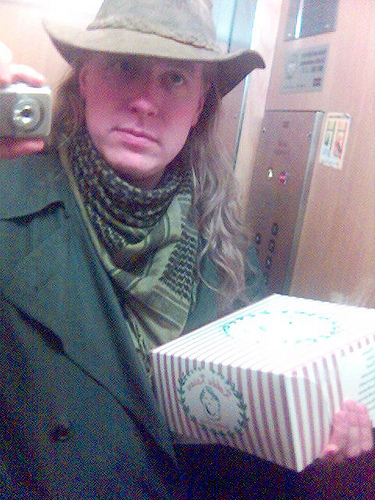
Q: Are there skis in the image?
A: No, there are no skis.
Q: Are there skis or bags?
A: No, there are no skis or bags.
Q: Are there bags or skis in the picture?
A: No, there are no skis or bags.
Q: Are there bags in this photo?
A: No, there are no bags.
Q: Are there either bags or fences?
A: No, there are no bags or fences.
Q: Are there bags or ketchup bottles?
A: No, there are no bags or ketchup bottles.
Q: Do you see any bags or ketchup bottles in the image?
A: No, there are no bags or ketchup bottles.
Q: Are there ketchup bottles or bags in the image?
A: No, there are no bags or ketchup bottles.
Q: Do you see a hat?
A: Yes, there is a hat.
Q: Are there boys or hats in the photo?
A: Yes, there is a hat.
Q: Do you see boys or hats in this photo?
A: Yes, there is a hat.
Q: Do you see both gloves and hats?
A: No, there is a hat but no gloves.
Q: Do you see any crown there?
A: No, there are no crowns.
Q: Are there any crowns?
A: No, there are no crowns.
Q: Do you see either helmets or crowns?
A: No, there are no crowns or helmets.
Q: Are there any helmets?
A: No, there are no helmets.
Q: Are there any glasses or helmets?
A: No, there are no helmets or glasses.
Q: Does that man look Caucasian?
A: Yes, the man is caucasian.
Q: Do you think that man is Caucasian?
A: Yes, the man is caucasian.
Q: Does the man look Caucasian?
A: Yes, the man is caucasian.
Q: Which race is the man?
A: The man is caucasian.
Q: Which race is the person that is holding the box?
A: The man is caucasian.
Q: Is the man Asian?
A: No, the man is caucasian.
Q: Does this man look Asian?
A: No, the man is caucasian.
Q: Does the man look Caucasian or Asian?
A: The man is caucasian.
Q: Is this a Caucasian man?
A: Yes, this is a Caucasian man.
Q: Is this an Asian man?
A: No, this is a Caucasian man.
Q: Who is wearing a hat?
A: The man is wearing a hat.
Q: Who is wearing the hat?
A: The man is wearing a hat.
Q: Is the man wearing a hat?
A: Yes, the man is wearing a hat.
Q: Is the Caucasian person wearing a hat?
A: Yes, the man is wearing a hat.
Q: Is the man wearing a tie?
A: No, the man is wearing a hat.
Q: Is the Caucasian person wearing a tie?
A: No, the man is wearing a hat.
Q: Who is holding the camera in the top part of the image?
A: The man is holding the camera.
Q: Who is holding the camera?
A: The man is holding the camera.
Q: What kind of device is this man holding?
A: The man is holding the camera.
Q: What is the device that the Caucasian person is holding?
A: The device is a camera.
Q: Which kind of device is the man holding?
A: The man is holding the camera.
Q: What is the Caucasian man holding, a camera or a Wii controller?
A: The man is holding a camera.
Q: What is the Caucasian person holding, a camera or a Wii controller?
A: The man is holding a camera.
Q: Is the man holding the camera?
A: Yes, the man is holding the camera.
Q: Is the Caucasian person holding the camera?
A: Yes, the man is holding the camera.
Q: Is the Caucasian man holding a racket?
A: No, the man is holding the camera.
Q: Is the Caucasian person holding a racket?
A: No, the man is holding the camera.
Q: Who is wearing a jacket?
A: The man is wearing a jacket.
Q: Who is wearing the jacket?
A: The man is wearing a jacket.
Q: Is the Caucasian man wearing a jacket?
A: Yes, the man is wearing a jacket.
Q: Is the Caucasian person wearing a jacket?
A: Yes, the man is wearing a jacket.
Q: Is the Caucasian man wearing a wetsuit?
A: No, the man is wearing a jacket.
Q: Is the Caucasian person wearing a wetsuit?
A: No, the man is wearing a jacket.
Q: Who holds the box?
A: The man holds the box.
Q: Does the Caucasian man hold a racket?
A: No, the man holds the box.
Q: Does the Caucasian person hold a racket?
A: No, the man holds the box.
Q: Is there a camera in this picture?
A: Yes, there is a camera.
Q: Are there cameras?
A: Yes, there is a camera.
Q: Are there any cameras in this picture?
A: Yes, there is a camera.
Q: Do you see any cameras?
A: Yes, there is a camera.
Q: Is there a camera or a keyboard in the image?
A: Yes, there is a camera.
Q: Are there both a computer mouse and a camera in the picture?
A: No, there is a camera but no computer mice.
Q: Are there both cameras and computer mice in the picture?
A: No, there is a camera but no computer mice.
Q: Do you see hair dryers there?
A: No, there are no hair dryers.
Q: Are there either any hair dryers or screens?
A: No, there are no hair dryers or screens.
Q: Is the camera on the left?
A: Yes, the camera is on the left of the image.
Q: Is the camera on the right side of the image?
A: No, the camera is on the left of the image.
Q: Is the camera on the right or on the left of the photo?
A: The camera is on the left of the image.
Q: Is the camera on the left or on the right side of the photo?
A: The camera is on the left of the image.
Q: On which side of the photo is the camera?
A: The camera is on the left of the image.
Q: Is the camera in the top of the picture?
A: Yes, the camera is in the top of the image.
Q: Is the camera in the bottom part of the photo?
A: No, the camera is in the top of the image.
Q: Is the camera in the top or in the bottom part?
A: The camera is in the top of the image.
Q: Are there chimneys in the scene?
A: No, there are no chimneys.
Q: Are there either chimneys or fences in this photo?
A: No, there are no chimneys or fences.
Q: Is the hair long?
A: Yes, the hair is long.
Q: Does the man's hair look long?
A: Yes, the hair is long.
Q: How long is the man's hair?
A: The hair is long.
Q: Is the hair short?
A: No, the hair is long.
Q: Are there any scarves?
A: Yes, there is a scarf.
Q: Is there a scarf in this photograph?
A: Yes, there is a scarf.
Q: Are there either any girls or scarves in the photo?
A: Yes, there is a scarf.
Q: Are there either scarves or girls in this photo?
A: Yes, there is a scarf.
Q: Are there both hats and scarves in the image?
A: Yes, there are both a scarf and a hat.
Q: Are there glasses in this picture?
A: No, there are no glasses.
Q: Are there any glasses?
A: No, there are no glasses.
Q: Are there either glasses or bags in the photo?
A: No, there are no glasses or bags.